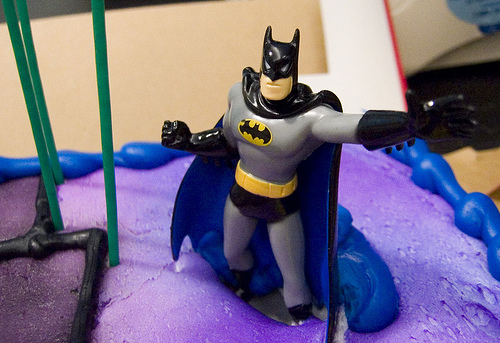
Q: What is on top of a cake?
A: A batman figure.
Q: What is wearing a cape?
A: The Batman figure.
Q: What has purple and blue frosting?
A: The cake.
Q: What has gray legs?
A: The Batman figure.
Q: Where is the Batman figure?
A: On the cake.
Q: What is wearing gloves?
A: The Batman figure.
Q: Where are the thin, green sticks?
A: In the cake.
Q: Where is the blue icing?
A: On the edge of the cake.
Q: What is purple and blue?
A: The cake.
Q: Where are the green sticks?
A: Next to the Batman figure.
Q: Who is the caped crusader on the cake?
A: Batman.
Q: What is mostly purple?
A: The cake.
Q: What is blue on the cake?
A: The edge.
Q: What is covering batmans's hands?
A: Gloves.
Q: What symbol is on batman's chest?
A: Bat.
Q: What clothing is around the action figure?
A: Cape.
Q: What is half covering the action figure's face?
A: Mask.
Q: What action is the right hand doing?
A: Making a fist.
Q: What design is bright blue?
A: The border.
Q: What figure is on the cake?
A: Batman.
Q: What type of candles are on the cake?
A: Tall green candles.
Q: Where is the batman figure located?
A: On the cake.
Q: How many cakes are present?
A: One.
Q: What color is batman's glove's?
A: Black.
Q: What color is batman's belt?
A: Yellow.